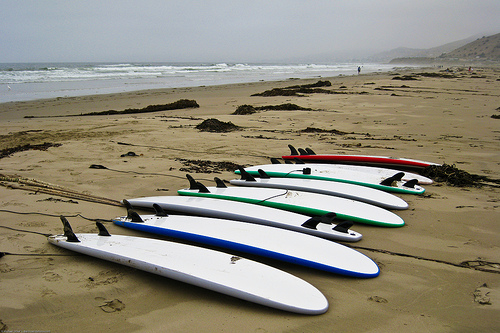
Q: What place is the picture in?
A: It is at the beach.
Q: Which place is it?
A: It is a beach.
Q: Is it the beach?
A: Yes, it is the beach.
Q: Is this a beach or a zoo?
A: It is a beach.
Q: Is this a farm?
A: No, it is a beach.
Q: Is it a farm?
A: No, it is a beach.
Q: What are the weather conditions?
A: It is overcast.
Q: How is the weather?
A: It is overcast.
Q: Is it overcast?
A: Yes, it is overcast.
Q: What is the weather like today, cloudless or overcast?
A: It is overcast.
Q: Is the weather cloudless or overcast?
A: It is overcast.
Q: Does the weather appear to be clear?
A: No, it is overcast.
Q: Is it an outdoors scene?
A: Yes, it is outdoors.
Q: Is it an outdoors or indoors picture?
A: It is outdoors.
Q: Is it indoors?
A: No, it is outdoors.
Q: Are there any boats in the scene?
A: No, there are no boats.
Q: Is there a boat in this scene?
A: No, there are no boats.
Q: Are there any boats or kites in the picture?
A: No, there are no boats or kites.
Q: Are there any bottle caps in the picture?
A: No, there are no bottle caps.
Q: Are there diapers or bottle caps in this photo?
A: No, there are no bottle caps or diapers.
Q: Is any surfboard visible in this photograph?
A: Yes, there is a surfboard.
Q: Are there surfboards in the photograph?
A: Yes, there is a surfboard.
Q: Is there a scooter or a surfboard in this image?
A: Yes, there is a surfboard.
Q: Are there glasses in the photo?
A: No, there are no glasses.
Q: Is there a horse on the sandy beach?
A: No, there is a surfboard on the beach.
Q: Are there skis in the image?
A: No, there are no skis.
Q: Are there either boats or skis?
A: No, there are no skis or boats.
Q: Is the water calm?
A: Yes, the water is calm.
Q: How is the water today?
A: The water is calm.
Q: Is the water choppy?
A: No, the water is calm.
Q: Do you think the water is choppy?
A: No, the water is calm.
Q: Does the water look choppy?
A: No, the water is calm.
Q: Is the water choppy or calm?
A: The water is calm.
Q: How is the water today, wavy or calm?
A: The water is calm.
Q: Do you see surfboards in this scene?
A: Yes, there is a surfboard.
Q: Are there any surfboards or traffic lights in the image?
A: Yes, there is a surfboard.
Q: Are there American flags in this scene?
A: No, there are no American flags.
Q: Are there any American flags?
A: No, there are no American flags.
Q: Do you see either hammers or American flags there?
A: No, there are no American flags or hammers.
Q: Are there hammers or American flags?
A: No, there are no American flags or hammers.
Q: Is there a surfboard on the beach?
A: Yes, there is a surfboard on the beach.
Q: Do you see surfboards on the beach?
A: Yes, there is a surfboard on the beach.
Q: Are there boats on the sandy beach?
A: No, there is a surfboard on the beach.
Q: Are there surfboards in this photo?
A: Yes, there is a surfboard.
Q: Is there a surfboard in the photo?
A: Yes, there is a surfboard.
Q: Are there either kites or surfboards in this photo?
A: Yes, there is a surfboard.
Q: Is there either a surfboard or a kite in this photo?
A: Yes, there is a surfboard.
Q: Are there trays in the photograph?
A: No, there are no trays.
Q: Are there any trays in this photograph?
A: No, there are no trays.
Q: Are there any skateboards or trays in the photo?
A: No, there are no trays or skateboards.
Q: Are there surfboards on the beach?
A: Yes, there is a surfboard on the beach.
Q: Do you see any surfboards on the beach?
A: Yes, there is a surfboard on the beach.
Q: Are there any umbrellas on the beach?
A: No, there is a surfboard on the beach.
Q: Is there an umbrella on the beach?
A: No, there is a surfboard on the beach.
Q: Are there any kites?
A: No, there are no kites.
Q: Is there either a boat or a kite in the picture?
A: No, there are no kites or boats.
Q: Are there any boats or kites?
A: No, there are no kites or boats.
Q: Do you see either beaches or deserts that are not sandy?
A: No, there is a beach but it is sandy.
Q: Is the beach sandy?
A: Yes, the beach is sandy.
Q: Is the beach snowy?
A: No, the beach is sandy.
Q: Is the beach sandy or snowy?
A: The beach is sandy.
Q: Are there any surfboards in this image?
A: Yes, there is a surfboard.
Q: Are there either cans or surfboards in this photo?
A: Yes, there is a surfboard.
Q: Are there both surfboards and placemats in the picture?
A: No, there is a surfboard but no placemats.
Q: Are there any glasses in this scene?
A: No, there are no glasses.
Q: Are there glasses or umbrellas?
A: No, there are no glasses or umbrellas.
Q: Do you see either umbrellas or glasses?
A: No, there are no glasses or umbrellas.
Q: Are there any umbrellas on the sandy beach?
A: No, there is a surfboard on the beach.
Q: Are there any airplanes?
A: No, there are no airplanes.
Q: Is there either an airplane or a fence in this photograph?
A: No, there are no airplanes or fences.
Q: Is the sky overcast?
A: Yes, the sky is overcast.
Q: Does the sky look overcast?
A: Yes, the sky is overcast.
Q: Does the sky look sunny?
A: No, the sky is overcast.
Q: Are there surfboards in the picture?
A: Yes, there is a surfboard.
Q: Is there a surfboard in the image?
A: Yes, there is a surfboard.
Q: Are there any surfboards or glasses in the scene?
A: Yes, there is a surfboard.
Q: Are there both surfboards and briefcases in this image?
A: No, there is a surfboard but no briefcases.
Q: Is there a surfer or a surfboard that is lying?
A: Yes, the surfboard is lying.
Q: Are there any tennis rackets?
A: No, there are no tennis rackets.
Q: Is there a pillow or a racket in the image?
A: No, there are no rackets or pillows.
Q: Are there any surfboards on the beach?
A: Yes, there is a surfboard on the beach.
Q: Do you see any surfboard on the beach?
A: Yes, there is a surfboard on the beach.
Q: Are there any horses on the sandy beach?
A: No, there is a surfboard on the beach.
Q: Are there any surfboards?
A: Yes, there is a surfboard.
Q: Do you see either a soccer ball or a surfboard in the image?
A: Yes, there is a surfboard.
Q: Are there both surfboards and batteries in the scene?
A: No, there is a surfboard but no batteries.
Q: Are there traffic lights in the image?
A: No, there are no traffic lights.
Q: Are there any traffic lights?
A: No, there are no traffic lights.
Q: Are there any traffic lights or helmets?
A: No, there are no traffic lights or helmets.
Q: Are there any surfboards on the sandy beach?
A: Yes, there is a surfboard on the beach.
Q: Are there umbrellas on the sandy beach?
A: No, there is a surfboard on the beach.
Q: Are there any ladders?
A: No, there are no ladders.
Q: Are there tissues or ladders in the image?
A: No, there are no ladders or tissues.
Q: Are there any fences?
A: No, there are no fences.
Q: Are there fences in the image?
A: No, there are no fences.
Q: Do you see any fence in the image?
A: No, there are no fences.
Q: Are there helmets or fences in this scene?
A: No, there are no fences or helmets.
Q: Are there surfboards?
A: Yes, there is a surfboard.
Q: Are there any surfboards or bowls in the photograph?
A: Yes, there is a surfboard.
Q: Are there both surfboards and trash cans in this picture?
A: No, there is a surfboard but no trash cans.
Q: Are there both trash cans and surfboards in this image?
A: No, there is a surfboard but no trash cans.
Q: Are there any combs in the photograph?
A: No, there are no combs.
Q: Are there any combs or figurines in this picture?
A: No, there are no combs or figurines.